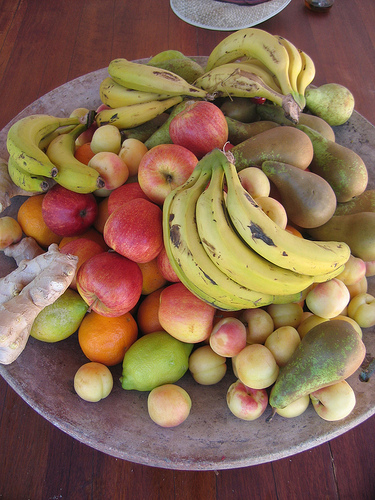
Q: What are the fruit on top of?
A: A platter.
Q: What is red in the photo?
A: Apples.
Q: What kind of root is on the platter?
A: Ginger.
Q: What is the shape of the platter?
A: Circle.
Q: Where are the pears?
A: Right side of platter.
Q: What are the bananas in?
A: A bunch.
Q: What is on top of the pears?
A: A stem.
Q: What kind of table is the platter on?
A: Wood.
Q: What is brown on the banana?
A: Ripe spots.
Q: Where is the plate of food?
A: On a table.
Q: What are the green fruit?
A: Limes.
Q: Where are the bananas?
A: On the platter.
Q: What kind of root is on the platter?
A: Ginger.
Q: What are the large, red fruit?
A: Apples.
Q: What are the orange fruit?
A: Oranges.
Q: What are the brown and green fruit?
A: Pears.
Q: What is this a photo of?
A: Fruit.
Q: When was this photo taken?
A: During the day.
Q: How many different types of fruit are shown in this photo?
A: Six.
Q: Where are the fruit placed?
A: In a large bowl.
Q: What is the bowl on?
A: A table.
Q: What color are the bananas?
A: Yellow.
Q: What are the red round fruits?
A: Apples.